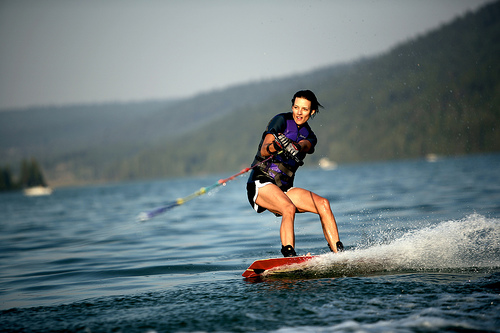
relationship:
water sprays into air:
[345, 214, 490, 276] [346, 206, 455, 247]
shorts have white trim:
[242, 180, 295, 212] [246, 185, 274, 220]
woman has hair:
[241, 75, 358, 259] [293, 84, 324, 109]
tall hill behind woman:
[321, 0, 489, 161] [241, 75, 358, 259]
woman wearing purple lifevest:
[241, 75, 358, 259] [254, 125, 322, 184]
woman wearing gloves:
[241, 75, 358, 259] [271, 136, 304, 158]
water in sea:
[345, 214, 490, 276] [4, 174, 489, 262]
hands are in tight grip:
[263, 135, 302, 161] [263, 130, 305, 166]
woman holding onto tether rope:
[241, 75, 358, 259] [125, 159, 256, 229]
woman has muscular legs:
[241, 75, 358, 259] [248, 173, 347, 261]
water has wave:
[345, 214, 490, 276] [332, 265, 479, 298]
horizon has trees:
[51, 150, 490, 164] [309, 61, 500, 170]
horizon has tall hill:
[51, 150, 490, 164] [321, 0, 489, 161]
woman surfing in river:
[241, 75, 358, 259] [1, 190, 458, 309]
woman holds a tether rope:
[241, 75, 358, 259] [125, 159, 256, 229]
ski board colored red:
[229, 241, 381, 293] [240, 242, 322, 286]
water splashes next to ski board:
[345, 214, 490, 276] [229, 241, 381, 293]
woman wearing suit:
[241, 75, 358, 259] [238, 127, 333, 215]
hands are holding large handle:
[263, 135, 302, 161] [266, 129, 311, 171]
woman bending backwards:
[241, 75, 358, 259] [210, 103, 352, 296]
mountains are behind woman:
[321, 0, 489, 161] [241, 75, 358, 259]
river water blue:
[1, 190, 458, 309] [13, 175, 231, 312]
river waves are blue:
[1, 190, 458, 309] [13, 175, 231, 312]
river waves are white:
[1, 190, 458, 309] [339, 230, 480, 333]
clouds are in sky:
[33, 3, 254, 67] [90, 1, 372, 45]